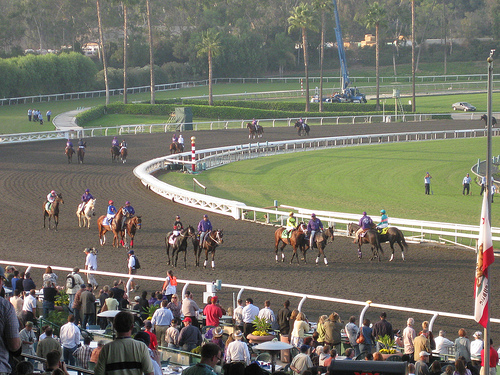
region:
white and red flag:
[474, 189, 495, 329]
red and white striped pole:
[189, 136, 196, 172]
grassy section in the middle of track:
[153, 135, 498, 249]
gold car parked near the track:
[451, 102, 473, 113]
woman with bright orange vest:
[161, 268, 177, 300]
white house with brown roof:
[81, 42, 98, 57]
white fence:
[1, 259, 498, 365]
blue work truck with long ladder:
[318, 1, 365, 104]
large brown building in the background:
[358, 32, 375, 47]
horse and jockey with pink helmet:
[41, 189, 64, 230]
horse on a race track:
[40, 186, 67, 230]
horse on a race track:
[72, 189, 96, 229]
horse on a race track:
[94, 198, 129, 247]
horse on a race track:
[120, 200, 145, 245]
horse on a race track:
[165, 210, 192, 270]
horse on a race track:
[192, 214, 224, 269]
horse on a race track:
[272, 208, 309, 261]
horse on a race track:
[301, 211, 338, 264]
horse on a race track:
[343, 210, 383, 262]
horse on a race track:
[374, 206, 409, 259]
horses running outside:
[15, 54, 447, 319]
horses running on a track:
[29, 48, 496, 363]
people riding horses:
[44, 66, 419, 370]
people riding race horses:
[19, 54, 429, 344]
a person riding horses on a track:
[37, 87, 480, 360]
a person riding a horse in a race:
[4, 20, 492, 370]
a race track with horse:
[19, 46, 418, 372]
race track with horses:
[22, 61, 334, 371]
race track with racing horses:
[27, 48, 476, 343]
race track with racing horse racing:
[47, 40, 465, 374]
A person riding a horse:
[61, 133, 74, 166]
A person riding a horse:
[76, 132, 89, 170]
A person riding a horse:
[108, 132, 120, 164]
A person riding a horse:
[117, 134, 129, 169]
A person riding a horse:
[165, 128, 178, 153]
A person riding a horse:
[242, 115, 269, 145]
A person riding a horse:
[290, 112, 316, 139]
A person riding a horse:
[38, 184, 69, 235]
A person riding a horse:
[74, 187, 97, 232]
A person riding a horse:
[161, 212, 194, 274]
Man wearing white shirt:
[226, 329, 253, 364]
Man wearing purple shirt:
[198, 213, 212, 244]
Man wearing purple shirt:
[310, 214, 322, 246]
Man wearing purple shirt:
[353, 210, 373, 244]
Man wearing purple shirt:
[78, 188, 95, 215]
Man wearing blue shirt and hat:
[377, 208, 389, 235]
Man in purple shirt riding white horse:
[76, 188, 96, 230]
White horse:
[77, 196, 97, 226]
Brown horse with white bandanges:
[191, 226, 227, 268]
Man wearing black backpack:
[125, 248, 140, 273]